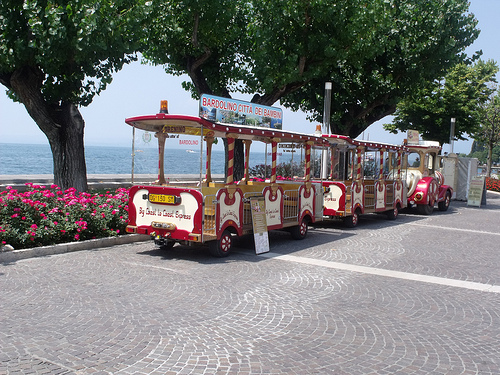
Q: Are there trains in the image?
A: Yes, there is a train.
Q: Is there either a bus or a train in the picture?
A: Yes, there is a train.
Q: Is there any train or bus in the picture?
A: Yes, there is a train.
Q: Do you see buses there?
A: No, there are no buses.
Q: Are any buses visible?
A: No, there are no buses.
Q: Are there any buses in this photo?
A: No, there are no buses.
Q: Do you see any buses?
A: No, there are no buses.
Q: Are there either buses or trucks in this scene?
A: No, there are no buses or trucks.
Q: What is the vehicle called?
A: The vehicle is a train.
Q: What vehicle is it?
A: The vehicle is a train.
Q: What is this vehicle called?
A: That is a train.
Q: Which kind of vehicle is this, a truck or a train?
A: That is a train.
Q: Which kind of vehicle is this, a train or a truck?
A: That is a train.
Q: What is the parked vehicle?
A: The vehicle is a train.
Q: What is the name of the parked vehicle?
A: The vehicle is a train.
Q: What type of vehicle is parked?
A: The vehicle is a train.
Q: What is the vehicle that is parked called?
A: The vehicle is a train.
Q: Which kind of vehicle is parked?
A: The vehicle is a train.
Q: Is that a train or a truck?
A: That is a train.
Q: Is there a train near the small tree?
A: Yes, there is a train near the tree.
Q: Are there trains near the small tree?
A: Yes, there is a train near the tree.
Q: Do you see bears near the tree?
A: No, there is a train near the tree.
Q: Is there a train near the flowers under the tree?
A: Yes, there is a train near the flowers.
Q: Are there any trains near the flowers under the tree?
A: Yes, there is a train near the flowers.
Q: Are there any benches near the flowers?
A: No, there is a train near the flowers.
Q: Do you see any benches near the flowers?
A: No, there is a train near the flowers.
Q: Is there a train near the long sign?
A: Yes, there is a train near the sign.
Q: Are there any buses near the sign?
A: No, there is a train near the sign.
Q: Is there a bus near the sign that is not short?
A: No, there is a train near the sign.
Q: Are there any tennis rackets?
A: No, there are no tennis rackets.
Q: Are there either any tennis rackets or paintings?
A: No, there are no tennis rackets or paintings.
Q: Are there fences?
A: No, there are no fences.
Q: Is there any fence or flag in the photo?
A: No, there are no fences or flags.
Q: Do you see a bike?
A: No, there are no bikes.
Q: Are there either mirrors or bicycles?
A: No, there are no bicycles or mirrors.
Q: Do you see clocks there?
A: No, there are no clocks.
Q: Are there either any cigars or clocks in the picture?
A: No, there are no clocks or cigars.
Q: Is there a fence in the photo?
A: No, there are no fences.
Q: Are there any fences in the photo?
A: No, there are no fences.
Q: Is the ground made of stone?
A: Yes, the ground is made of stone.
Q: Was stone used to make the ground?
A: Yes, the ground is made of stone.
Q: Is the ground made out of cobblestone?
A: No, the ground is made of stone.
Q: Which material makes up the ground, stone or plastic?
A: The ground is made of stone.